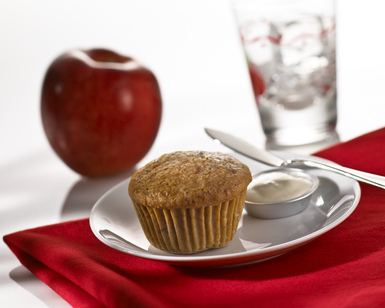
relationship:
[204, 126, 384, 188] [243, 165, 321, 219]
knife for container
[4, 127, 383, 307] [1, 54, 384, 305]
napkin on table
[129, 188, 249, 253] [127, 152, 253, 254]
wrapper on muffin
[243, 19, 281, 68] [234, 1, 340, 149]
ice in glass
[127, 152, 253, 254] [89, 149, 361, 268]
muffin on plate